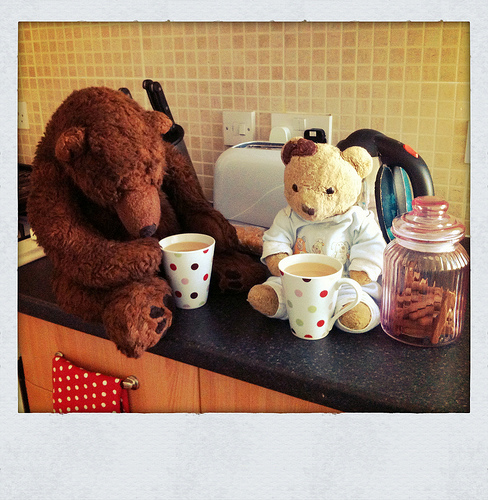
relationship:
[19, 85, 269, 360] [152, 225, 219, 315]
bear beside cup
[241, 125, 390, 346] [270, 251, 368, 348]
bear beside cup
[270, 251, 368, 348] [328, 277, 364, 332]
cup has handle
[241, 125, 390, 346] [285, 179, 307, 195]
bear has eye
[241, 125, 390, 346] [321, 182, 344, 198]
bear has eye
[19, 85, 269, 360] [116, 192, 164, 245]
bear has nose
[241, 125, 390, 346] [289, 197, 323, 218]
bear has nose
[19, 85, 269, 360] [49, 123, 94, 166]
bear has ear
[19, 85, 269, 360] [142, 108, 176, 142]
bear has ear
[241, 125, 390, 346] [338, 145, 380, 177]
bear has ear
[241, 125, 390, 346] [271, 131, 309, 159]
bear has ear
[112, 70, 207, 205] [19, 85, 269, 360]
knives behind bear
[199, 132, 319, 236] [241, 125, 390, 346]
toaster behind bear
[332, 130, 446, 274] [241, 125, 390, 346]
iron behind bear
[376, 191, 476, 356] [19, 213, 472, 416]
jar on counter